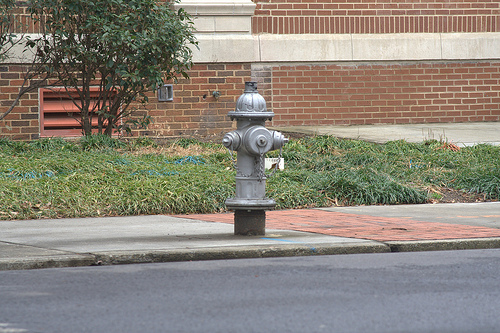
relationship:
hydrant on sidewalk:
[203, 67, 291, 236] [164, 221, 202, 237]